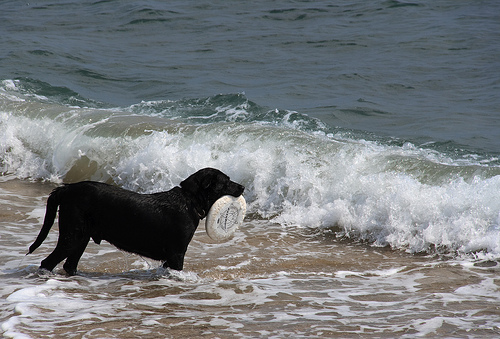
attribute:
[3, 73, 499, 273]
wave — small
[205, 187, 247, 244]
frisbee — white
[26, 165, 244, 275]
dog — black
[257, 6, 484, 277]
water — murky